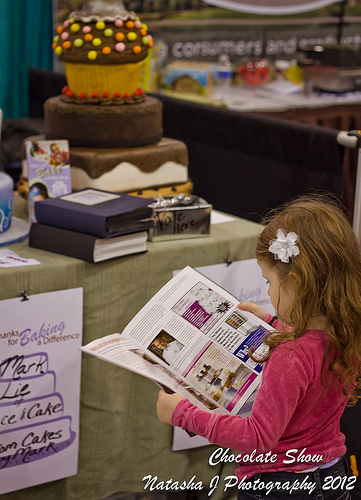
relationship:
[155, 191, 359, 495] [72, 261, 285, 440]
girl reading magazine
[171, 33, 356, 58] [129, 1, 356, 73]
sign posted window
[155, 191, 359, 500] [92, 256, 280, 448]
girl reading brochure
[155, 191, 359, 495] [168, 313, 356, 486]
girl in shirt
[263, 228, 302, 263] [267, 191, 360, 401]
flower in hair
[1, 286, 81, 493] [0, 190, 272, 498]
sign on table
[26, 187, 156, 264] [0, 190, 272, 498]
books on table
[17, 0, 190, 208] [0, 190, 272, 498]
cake on table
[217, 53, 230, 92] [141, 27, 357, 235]
bottle on table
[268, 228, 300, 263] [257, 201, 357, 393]
flower in hair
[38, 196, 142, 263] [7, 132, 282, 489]
books laying on table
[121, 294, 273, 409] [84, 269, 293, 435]
picture in magazine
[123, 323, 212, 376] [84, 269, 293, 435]
man in magazine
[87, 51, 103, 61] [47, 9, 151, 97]
ball on cupcake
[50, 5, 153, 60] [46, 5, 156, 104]
frosting on cupcake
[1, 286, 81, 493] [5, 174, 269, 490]
sign hanging on table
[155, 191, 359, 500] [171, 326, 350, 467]
girl wearing shirt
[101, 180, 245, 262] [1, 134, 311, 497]
ballot box on table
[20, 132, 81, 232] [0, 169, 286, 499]
brochure on table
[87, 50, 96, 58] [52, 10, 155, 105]
sprinkles on cupcake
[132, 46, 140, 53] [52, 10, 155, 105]
sprinkles on cupcake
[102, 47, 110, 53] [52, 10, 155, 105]
sprinkles on cupcake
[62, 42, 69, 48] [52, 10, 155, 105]
sprinkles on cupcake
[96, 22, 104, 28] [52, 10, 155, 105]
sprinkles on cupcake